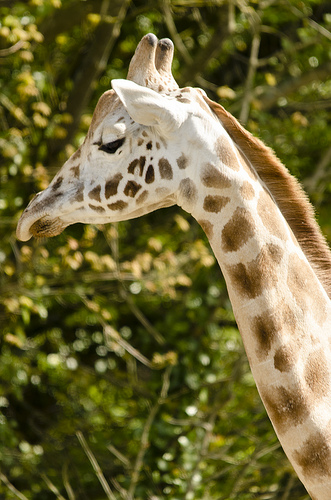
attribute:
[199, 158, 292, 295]
brown spots — on giraffe's neck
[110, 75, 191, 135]
giraffe ear — white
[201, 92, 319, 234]
brown mane — on giraffe's neck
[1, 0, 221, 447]
trees — behind the giraffe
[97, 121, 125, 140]
white eyelid — of the giraffe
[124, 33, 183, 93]
short horns — of the giraffe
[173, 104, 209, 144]
white spot — on giraffe's head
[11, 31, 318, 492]
giraffe — standing in front of green trees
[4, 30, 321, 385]
head/neck — of giraffe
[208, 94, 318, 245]
short hair/mane — on giraffe's neck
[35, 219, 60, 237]
bottom lip — of giraffe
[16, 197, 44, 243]
top lip — of giraffe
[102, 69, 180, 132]
ear — white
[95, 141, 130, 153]
eyelashes — black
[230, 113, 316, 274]
hair — brown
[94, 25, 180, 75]
horns — tiny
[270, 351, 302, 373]
spot — brown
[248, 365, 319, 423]
spot — brown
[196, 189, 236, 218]
spot — brown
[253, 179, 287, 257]
spot — brown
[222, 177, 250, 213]
spot — brown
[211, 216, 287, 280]
spot — brown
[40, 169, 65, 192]
spot — brown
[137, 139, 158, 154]
spot — brown